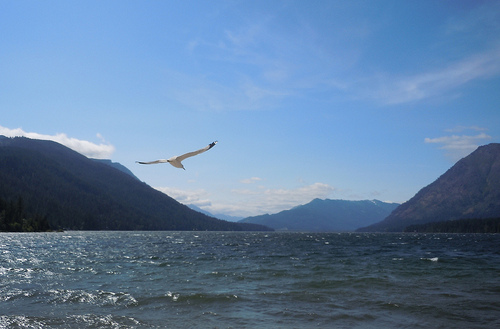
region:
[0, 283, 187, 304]
reflection of the light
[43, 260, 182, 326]
ripples on the water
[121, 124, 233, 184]
bird in the sky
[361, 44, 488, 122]
cloud in the sky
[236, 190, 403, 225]
mountain against the sky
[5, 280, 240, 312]
wave in the water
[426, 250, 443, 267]
crest of a wave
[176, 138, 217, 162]
wing of a bird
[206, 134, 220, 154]
tip of the wing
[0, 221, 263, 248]
shore line of the water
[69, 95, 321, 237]
a bird flying in the air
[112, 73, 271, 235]
a bird flying in the sky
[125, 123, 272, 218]
a white bird flying in the air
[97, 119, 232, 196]
a white bird flying in the sky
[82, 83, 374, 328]
a bird flying above the water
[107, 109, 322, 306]
a white bird flying above the water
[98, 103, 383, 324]
a bird flying above a body of water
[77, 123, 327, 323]
a white bird flying above a body of water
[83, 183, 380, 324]
a body of water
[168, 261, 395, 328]
a body of calm water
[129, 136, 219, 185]
bird flying over water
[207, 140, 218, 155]
black tip of bird's wing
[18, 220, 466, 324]
water bird is flying over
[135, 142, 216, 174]
white bird with wings extended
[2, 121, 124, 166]
cloud on left side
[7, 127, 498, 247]
mountains on left and right side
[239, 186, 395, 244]
mountain on the horizon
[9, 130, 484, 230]
three mountains on the water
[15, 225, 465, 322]
ripples in the water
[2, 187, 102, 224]
plants growing by mountain on left side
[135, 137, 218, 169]
black and white bird flying over the water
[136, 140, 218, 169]
sea gull flying over the ocean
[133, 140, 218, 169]
bird looking for fish in the water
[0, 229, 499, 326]
body of calm water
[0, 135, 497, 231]
mountain ranges in the distance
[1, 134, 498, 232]
trees growing on the mountains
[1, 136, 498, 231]
trees growing by the water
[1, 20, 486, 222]
clouds in the blue sky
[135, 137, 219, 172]
bird hoovering over the water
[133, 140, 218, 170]
black and white bird gliding over the water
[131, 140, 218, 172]
White bird flying over water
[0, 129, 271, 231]
Green mountain next to water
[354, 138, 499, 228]
Green mountain next to water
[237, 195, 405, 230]
Mountain far from water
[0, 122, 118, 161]
White cloud in blue sky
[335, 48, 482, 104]
Wisp of cloud in sky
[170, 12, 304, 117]
Wisp of cloud in sky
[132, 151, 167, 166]
Wing of bird is extended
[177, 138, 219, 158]
Wing of bird is extended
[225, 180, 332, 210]
White cloud behind mountain